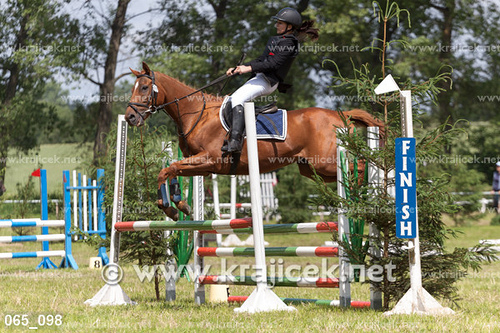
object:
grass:
[0, 140, 498, 330]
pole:
[195, 244, 340, 256]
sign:
[392, 136, 419, 239]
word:
[399, 136, 414, 236]